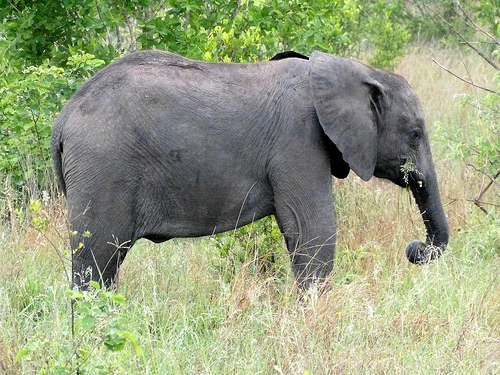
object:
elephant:
[49, 50, 452, 302]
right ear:
[308, 50, 382, 182]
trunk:
[404, 158, 450, 266]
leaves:
[401, 169, 405, 172]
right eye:
[409, 123, 424, 142]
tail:
[47, 115, 69, 198]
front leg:
[263, 141, 335, 292]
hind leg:
[65, 163, 138, 292]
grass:
[2, 49, 499, 371]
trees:
[365, 0, 413, 74]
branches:
[430, 57, 499, 96]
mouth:
[397, 156, 417, 197]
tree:
[26, 203, 129, 372]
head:
[311, 43, 449, 267]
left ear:
[268, 51, 349, 183]